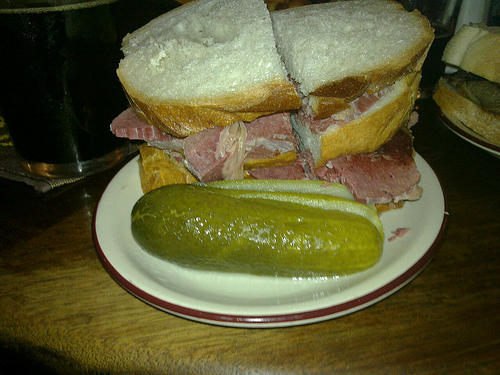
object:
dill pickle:
[130, 178, 386, 279]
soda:
[6, 18, 114, 147]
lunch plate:
[91, 148, 450, 329]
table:
[1, 158, 499, 373]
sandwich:
[114, 0, 436, 195]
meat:
[109, 77, 422, 208]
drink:
[0, 1, 141, 181]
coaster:
[0, 137, 137, 191]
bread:
[115, 2, 436, 191]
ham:
[108, 88, 422, 209]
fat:
[215, 121, 248, 180]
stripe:
[89, 147, 448, 329]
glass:
[2, 2, 127, 177]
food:
[109, 0, 500, 283]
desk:
[0, 120, 496, 370]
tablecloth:
[2, 160, 114, 194]